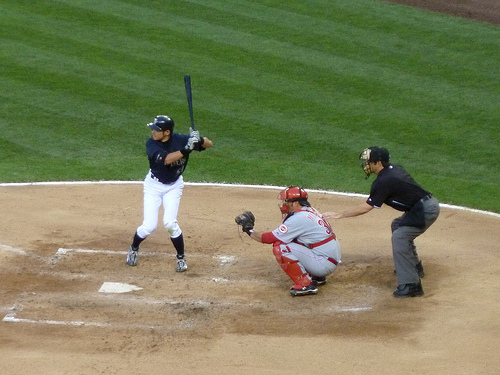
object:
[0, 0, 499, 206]
grass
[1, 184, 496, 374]
dirt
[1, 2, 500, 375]
field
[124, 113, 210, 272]
player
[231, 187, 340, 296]
catcher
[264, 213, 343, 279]
uniform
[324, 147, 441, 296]
umpire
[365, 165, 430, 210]
shirt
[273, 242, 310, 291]
shin guards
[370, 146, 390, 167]
hat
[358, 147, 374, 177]
face mask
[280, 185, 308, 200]
helmet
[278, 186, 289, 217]
mask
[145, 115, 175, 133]
helmet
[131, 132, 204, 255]
uniform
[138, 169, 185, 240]
pants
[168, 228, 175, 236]
dirt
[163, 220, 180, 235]
knee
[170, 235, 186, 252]
sock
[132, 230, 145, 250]
sock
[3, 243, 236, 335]
box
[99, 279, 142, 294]
home plate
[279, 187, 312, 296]
gear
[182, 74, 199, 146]
bat